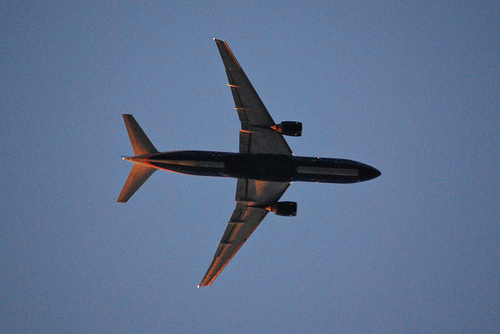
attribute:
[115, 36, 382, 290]
airplane — flying, black, silver, large, flying eastward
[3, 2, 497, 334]
sky — blue, clear, violet blue, cloudless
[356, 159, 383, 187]
nose — pointed, tapered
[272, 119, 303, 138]
engine — turbine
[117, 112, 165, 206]
tail — glowing, smaller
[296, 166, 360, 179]
area — white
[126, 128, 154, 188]
reflection — reddish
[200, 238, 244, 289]
reflection — reddish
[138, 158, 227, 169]
stripe — white